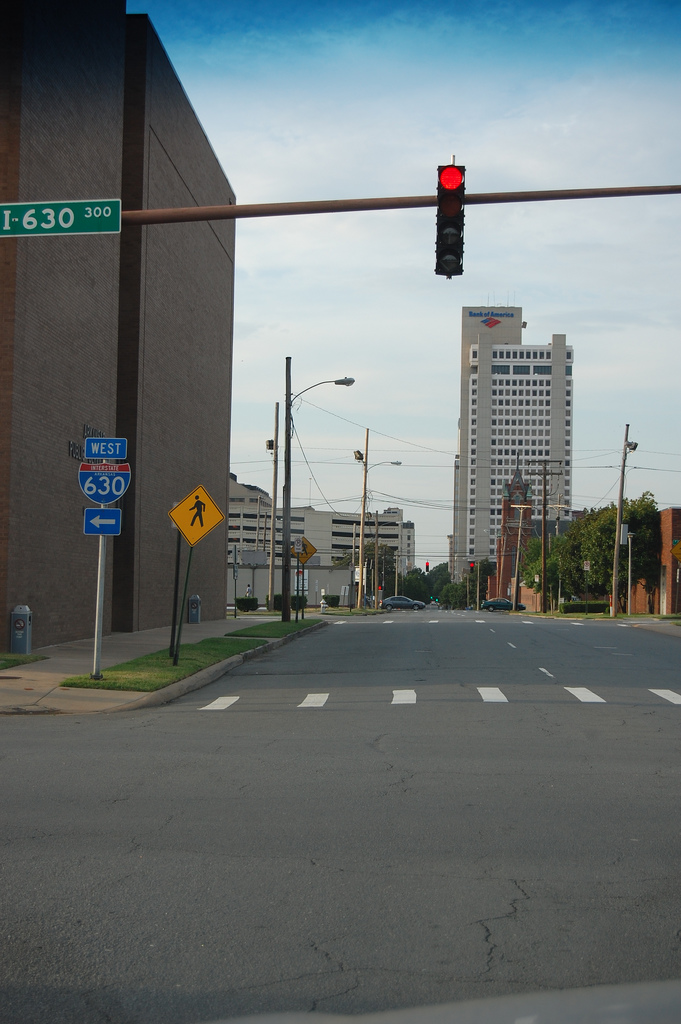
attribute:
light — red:
[419, 131, 488, 218]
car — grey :
[355, 573, 473, 644]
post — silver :
[68, 423, 193, 756]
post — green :
[73, 399, 189, 673]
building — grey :
[456, 286, 609, 624]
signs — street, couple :
[67, 435, 133, 561]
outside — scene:
[9, 102, 660, 889]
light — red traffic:
[428, 151, 480, 281]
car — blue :
[376, 589, 424, 612]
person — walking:
[312, 570, 339, 605]